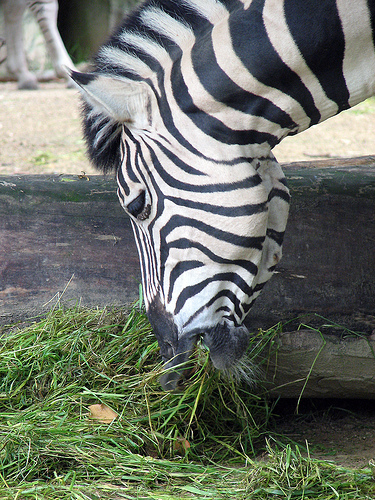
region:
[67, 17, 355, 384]
The zebra is black and white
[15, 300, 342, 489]
The hay is on the ground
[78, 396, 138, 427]
The leaf is brown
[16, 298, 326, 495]
The hay is green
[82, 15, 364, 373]
The zebra is eating the hay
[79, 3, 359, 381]
The zebra is grazing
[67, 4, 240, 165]
The zebra has a short mane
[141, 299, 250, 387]
The zebra has a black muzzle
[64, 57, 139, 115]
The zebra has white ears with black tips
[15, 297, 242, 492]
The hay is on the dirt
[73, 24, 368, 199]
this is a zebra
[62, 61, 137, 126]
this is the ear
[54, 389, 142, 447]
this is a grass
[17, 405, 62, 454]
the grass is green in color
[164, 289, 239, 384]
this is the mouth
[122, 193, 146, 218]
this is the eye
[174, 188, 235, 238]
the zebra has white and black strips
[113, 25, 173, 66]
this is the fur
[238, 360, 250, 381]
the fur is white in color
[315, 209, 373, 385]
this is a rock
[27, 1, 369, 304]
this is a zebra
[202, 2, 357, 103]
this is a neck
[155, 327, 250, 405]
the zebra is feeding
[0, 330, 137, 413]
the grass is green in color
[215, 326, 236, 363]
the mouth is black in color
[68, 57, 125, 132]
this is the ear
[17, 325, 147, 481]
the grass are green in color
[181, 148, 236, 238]
the zebra is white and black in color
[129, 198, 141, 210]
this is the eye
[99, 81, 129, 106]
the ear is white in color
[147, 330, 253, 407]
Zebra mouth with grass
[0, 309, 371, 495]
Fresh green grass on the ground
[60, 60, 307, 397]
Head of an adult zebra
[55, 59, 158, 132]
pointing ear of a zebra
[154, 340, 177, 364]
Wide opening of a nostril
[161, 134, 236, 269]
Black and white stripes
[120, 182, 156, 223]
Partially closed hairy eyelid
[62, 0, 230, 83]
Long hair on the back of the neck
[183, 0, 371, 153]
Thick neck of a zebra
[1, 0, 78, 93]
Pair of zebra legs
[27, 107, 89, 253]
Groudn is grey color.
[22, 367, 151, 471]
Grass is green and brown color.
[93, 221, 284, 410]
Zebra is eating the grass.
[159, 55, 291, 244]
Zebra is white and black color.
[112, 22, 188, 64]
Zebra has short hairs on back.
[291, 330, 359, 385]
Log is brown color.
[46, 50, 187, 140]
Zebra has two pointed ears.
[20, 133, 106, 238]
Shadow falls on ground.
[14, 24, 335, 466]
Day time picture.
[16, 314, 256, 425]
Grass is lying in ground.